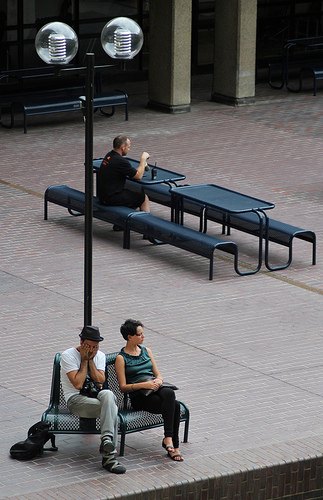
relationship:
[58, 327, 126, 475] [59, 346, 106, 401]
man wearing shirt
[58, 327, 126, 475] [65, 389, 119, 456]
man wearing jeans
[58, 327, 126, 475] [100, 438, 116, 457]
man wearing shoe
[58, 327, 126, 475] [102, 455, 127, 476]
man wearing shoe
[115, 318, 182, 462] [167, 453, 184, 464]
woman wearing sandal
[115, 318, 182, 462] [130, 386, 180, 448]
woman wearing pants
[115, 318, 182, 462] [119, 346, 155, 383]
woman wearing shirt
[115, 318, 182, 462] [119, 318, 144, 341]
woman has hair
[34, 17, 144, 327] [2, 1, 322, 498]
lamp post located in plaza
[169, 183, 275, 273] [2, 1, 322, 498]
table located in plaza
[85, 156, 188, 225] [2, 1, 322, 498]
table located in plaza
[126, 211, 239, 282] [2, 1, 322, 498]
bench located in plaza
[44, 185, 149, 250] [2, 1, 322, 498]
bench located in plaza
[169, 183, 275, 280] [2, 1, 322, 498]
table located in plaza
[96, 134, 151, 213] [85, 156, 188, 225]
man sitting at table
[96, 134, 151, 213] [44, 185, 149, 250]
man sitting on bench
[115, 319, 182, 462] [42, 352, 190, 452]
woman sitting on bench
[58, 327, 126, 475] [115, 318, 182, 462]
man sitting next to woman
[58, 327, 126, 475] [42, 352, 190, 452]
man sitting on bench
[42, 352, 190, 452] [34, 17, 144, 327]
bench in front of lamp post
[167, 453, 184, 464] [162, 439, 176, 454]
sandal worn on foot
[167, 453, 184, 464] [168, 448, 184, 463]
sandal worn on foot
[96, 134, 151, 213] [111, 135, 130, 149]
man has hair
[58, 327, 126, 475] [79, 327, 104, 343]
man wearing hat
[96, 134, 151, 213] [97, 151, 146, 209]
man wearing clothing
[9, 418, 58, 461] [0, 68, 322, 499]
backpack on top of ground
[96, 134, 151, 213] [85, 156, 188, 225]
man near table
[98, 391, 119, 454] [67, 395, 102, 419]
leg crossed over leg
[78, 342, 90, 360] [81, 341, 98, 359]
hand touching face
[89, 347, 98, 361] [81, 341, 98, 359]
hand touching face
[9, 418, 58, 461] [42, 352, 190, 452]
backpack slumped against bench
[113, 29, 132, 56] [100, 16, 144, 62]
spiral inside globe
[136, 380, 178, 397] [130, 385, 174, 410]
bag on top of lap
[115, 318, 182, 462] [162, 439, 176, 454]
woman has foot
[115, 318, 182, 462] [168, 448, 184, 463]
woman has foot